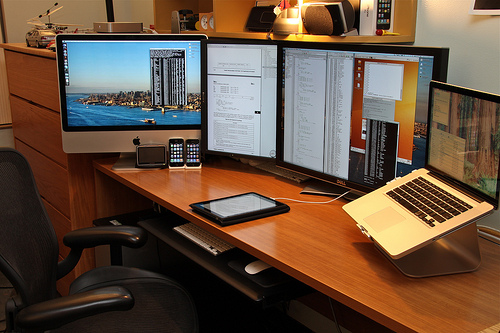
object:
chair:
[0, 146, 202, 333]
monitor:
[54, 32, 209, 155]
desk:
[91, 152, 500, 333]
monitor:
[199, 36, 279, 164]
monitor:
[274, 39, 449, 196]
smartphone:
[135, 143, 168, 168]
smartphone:
[168, 136, 185, 167]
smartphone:
[185, 137, 201, 167]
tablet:
[188, 191, 291, 228]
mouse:
[243, 258, 271, 276]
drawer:
[137, 211, 287, 302]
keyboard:
[172, 220, 236, 258]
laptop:
[340, 78, 499, 261]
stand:
[370, 219, 484, 279]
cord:
[273, 189, 352, 205]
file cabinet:
[1, 41, 118, 301]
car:
[25, 28, 58, 49]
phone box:
[357, 0, 395, 36]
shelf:
[150, 0, 418, 45]